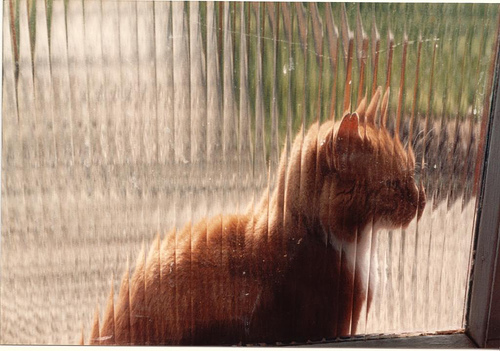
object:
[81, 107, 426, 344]
cat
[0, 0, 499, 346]
window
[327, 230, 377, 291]
white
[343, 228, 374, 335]
front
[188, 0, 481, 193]
grass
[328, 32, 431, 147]
reflection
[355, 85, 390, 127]
ears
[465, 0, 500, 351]
left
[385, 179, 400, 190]
eyes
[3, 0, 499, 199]
background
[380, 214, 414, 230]
chin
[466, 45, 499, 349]
door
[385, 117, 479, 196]
dirt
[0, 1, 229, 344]
concrete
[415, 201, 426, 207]
nose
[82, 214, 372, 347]
body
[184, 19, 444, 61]
scratch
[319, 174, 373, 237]
fur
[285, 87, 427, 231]
head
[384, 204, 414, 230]
whiskers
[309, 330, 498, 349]
trim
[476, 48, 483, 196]
stain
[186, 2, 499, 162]
yard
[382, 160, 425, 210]
face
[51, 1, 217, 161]
sidewalk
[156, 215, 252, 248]
back